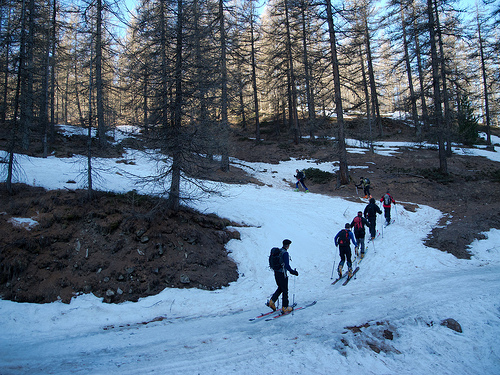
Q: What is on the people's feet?
A: Skis.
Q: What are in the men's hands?
A: Ski poles.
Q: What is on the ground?
A: Snow.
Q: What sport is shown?
A: Skiing.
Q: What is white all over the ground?
A: Snow.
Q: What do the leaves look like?
A: There are none.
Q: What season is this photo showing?
A: Winter.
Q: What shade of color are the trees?
A: Brown.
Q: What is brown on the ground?
A: Dirt.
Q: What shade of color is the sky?
A: Blue.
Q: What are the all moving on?
A: Skis.